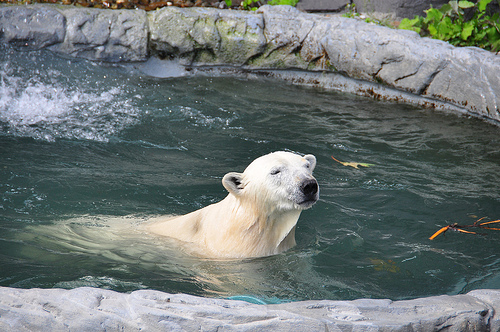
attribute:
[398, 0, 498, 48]
leaves — green 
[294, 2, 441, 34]
wall — rock 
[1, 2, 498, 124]
containment wall — man-made, stone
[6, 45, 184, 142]
water — splashing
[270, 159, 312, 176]
eyes — closed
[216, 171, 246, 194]
ear — perked up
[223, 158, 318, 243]
bear — White 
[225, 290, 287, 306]
object — blue 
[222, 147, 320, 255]
bear — white 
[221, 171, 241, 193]
ear — round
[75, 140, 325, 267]
polar bear — swimming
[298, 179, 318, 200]
nose — black 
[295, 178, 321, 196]
nose — black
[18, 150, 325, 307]
bear — white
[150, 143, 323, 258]
fur — wet